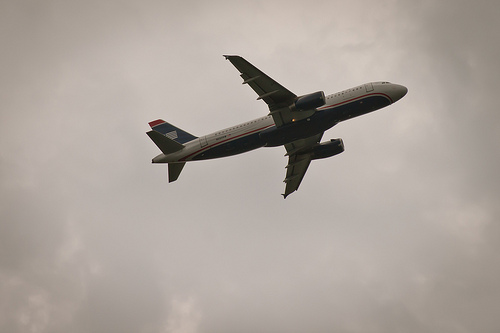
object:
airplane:
[144, 55, 408, 199]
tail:
[147, 117, 199, 183]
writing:
[216, 134, 229, 140]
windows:
[268, 116, 270, 118]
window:
[236, 126, 238, 128]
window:
[246, 122, 249, 125]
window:
[265, 117, 267, 120]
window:
[218, 132, 220, 134]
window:
[230, 128, 232, 131]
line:
[321, 92, 383, 110]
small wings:
[145, 131, 185, 155]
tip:
[148, 118, 166, 127]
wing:
[222, 53, 297, 99]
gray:
[342, 15, 399, 52]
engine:
[296, 91, 326, 111]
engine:
[313, 138, 344, 159]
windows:
[251, 121, 257, 125]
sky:
[0, 0, 499, 331]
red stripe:
[205, 124, 276, 149]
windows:
[254, 119, 260, 123]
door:
[365, 82, 373, 92]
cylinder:
[259, 127, 282, 139]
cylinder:
[265, 140, 282, 148]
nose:
[399, 86, 406, 91]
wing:
[281, 133, 323, 200]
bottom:
[192, 95, 385, 160]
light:
[291, 118, 296, 122]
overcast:
[53, 49, 226, 143]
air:
[37, 0, 491, 68]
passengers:
[213, 116, 264, 156]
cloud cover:
[308, 204, 498, 333]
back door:
[198, 135, 208, 148]